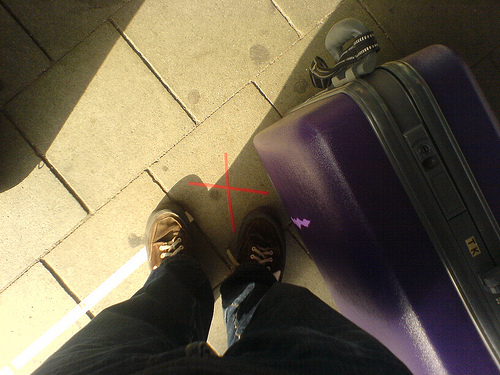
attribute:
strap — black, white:
[318, 49, 348, 85]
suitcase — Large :
[247, 29, 494, 371]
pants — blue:
[27, 266, 407, 373]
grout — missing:
[2, 110, 89, 215]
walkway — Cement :
[2, 0, 495, 375]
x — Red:
[185, 148, 275, 238]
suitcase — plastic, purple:
[267, 21, 498, 369]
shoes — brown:
[138, 197, 293, 299]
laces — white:
[153, 226, 278, 271]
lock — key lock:
[409, 132, 442, 171]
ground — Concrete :
[16, 46, 476, 316]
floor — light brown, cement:
[28, 22, 245, 202]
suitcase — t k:
[269, 64, 482, 236]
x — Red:
[185, 149, 269, 234]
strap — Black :
[302, 31, 395, 90]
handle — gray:
[321, 15, 374, 79]